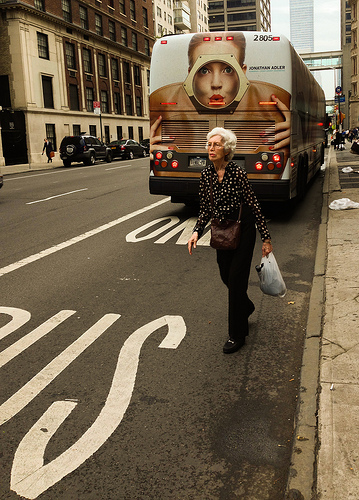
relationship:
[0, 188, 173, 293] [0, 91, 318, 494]
lines on road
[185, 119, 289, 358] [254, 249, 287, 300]
old woman carrying bag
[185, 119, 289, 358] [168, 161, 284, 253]
old woman wearing shirt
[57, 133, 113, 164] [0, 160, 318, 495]
car parked road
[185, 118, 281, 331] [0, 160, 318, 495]
old woman crossing road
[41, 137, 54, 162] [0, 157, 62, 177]
man walking on sidewalk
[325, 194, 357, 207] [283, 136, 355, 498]
trash on sidewalk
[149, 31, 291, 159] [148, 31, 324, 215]
lady on back of bus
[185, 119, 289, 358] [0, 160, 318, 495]
old woman walking down road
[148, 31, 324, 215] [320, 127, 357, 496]
bus stopped near a sidewalk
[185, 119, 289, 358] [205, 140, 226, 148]
old woman wearing glasses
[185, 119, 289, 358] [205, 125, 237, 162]
old woman has hair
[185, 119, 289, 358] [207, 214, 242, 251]
old woman carrying bag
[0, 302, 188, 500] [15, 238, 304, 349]
letters are on street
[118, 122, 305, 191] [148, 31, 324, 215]
lights are on bus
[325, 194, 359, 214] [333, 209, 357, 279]
trash are littering sidewalk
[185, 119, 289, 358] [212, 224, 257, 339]
old woman wearing pants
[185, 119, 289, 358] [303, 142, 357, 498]
old woman walking on sidewalk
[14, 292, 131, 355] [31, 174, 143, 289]
letters painted on street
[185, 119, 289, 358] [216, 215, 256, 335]
old woman wearing pants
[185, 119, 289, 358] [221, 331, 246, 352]
old woman wearing shoe